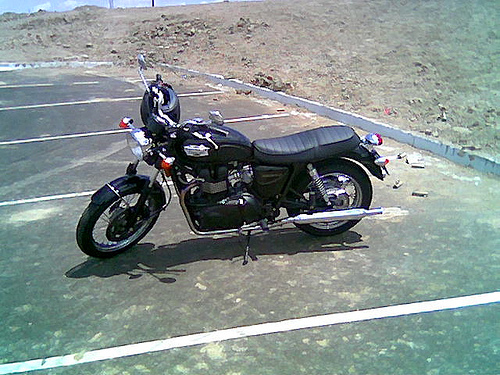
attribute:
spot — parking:
[2, 136, 494, 363]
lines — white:
[4, 63, 498, 356]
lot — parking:
[3, 58, 496, 371]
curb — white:
[151, 52, 498, 214]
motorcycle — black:
[72, 53, 391, 266]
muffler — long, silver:
[265, 206, 385, 232]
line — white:
[0, 289, 494, 373]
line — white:
[3, 112, 304, 144]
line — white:
[3, 76, 160, 88]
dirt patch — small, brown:
[149, 3, 497, 161]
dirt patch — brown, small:
[386, 60, 460, 125]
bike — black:
[66, 47, 398, 261]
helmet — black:
[133, 80, 187, 132]